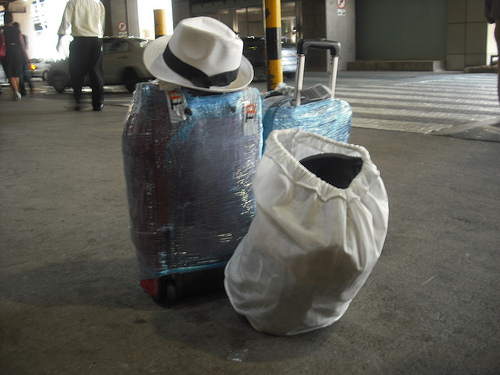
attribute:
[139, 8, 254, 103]
hat — gray, white, fedora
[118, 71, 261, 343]
suitcase — wrapped, blue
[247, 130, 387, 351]
bag — white, cloth, cotton, full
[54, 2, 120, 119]
man — standing, walking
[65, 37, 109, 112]
pants — black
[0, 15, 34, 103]
woman — walking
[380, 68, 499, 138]
crosswalk — white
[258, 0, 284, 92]
pillar — yellow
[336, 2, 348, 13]
sign — no-parking, white, do not smoke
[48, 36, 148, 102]
car — moving, white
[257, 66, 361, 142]
luggage — wrapped, red, grouped, grey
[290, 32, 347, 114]
handle — silver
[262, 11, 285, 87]
pole — traffic pole, yellow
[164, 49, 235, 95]
band — black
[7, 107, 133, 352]
walkway — cement